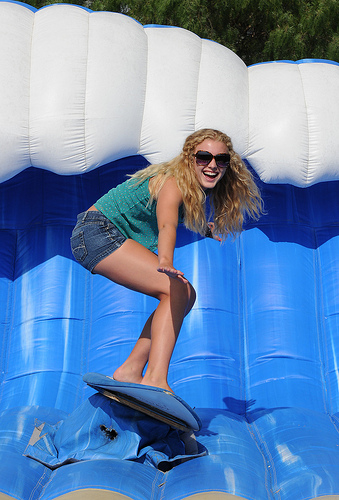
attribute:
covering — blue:
[2, 184, 338, 499]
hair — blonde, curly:
[132, 118, 277, 250]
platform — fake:
[59, 355, 245, 483]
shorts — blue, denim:
[71, 214, 111, 264]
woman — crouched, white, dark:
[68, 128, 264, 399]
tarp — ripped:
[0, 1, 337, 496]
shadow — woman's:
[200, 370, 293, 440]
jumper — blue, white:
[0, 0, 338, 499]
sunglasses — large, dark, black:
[180, 138, 268, 194]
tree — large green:
[299, 5, 332, 56]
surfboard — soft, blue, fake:
[81, 370, 201, 431]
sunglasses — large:
[189, 149, 230, 169]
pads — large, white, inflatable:
[242, 63, 302, 127]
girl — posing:
[67, 126, 268, 397]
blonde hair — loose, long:
[215, 164, 253, 219]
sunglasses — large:
[188, 148, 230, 165]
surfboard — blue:
[78, 358, 203, 437]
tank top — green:
[97, 173, 165, 247]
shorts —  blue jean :
[66, 206, 136, 267]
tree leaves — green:
[90, 0, 336, 61]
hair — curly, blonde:
[151, 133, 270, 240]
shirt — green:
[94, 169, 175, 253]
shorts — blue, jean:
[70, 210, 126, 274]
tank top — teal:
[93, 170, 157, 253]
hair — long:
[220, 148, 264, 237]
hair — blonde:
[170, 134, 206, 235]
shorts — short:
[64, 190, 138, 290]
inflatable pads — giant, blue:
[259, 212, 323, 297]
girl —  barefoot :
[51, 89, 285, 417]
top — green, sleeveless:
[90, 171, 185, 255]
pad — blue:
[4, 17, 336, 498]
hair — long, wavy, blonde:
[132, 125, 265, 242]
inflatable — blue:
[2, 2, 332, 496]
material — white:
[2, 33, 323, 159]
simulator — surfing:
[21, 369, 208, 463]